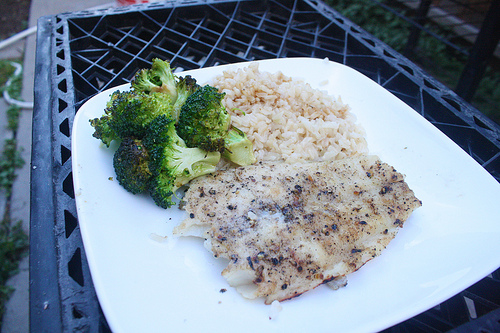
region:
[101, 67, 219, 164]
green broccoli on white plate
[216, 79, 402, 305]
cooked fish on white plate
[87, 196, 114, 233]
food on white plate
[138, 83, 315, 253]
food on white plate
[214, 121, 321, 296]
food on white plate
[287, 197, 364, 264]
chicken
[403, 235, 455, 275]
a white plate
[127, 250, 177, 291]
the plate is white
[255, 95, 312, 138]
rice is brown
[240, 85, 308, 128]
rice on the plate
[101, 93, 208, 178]
the brocolli is green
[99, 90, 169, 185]
the brocolli is on the plate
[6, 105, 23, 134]
the small bushes in the cracks of the ground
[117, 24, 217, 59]
a crate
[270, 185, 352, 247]
seasoning on the chicken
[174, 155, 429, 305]
piece of cooked peppered fish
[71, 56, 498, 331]
white square dinner plate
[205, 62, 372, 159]
pile of brown rice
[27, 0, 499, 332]
black wrought iron table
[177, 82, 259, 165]
piece of cooked broccoli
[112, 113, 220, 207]
piece of cooked broccoli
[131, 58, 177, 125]
piece of cooked broccoli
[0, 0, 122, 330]
grey concrete sidewalk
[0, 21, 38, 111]
grey garden hose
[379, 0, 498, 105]
black metal rack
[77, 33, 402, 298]
food on the plate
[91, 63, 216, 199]
broccoli on the plate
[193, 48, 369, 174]
rice on the plate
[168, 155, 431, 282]
chicken on the plate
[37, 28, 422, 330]
white plate on the grill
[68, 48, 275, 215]
broccoli on the plate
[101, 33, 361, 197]
rice and broccoli on a plate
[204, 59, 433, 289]
chicken and rice on a plate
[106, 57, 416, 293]
chicken rice and broccoli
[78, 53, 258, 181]
broccoli and rice on a plate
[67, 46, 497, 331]
one square white plate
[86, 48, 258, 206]
green broccoli on plate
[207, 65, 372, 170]
white rice on white plate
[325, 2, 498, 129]
green grass on ground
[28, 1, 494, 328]
black metal grate underneath plate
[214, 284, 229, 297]
black crumb on white plate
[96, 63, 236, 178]
brocolli on a white plate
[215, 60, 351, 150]
white rice with flavoring on a white plate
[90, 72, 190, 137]
brocolli on a white plate